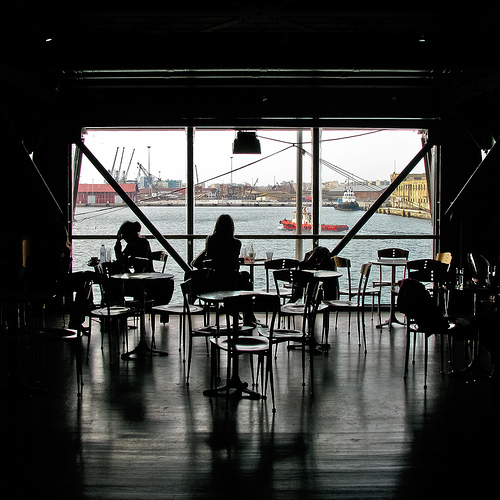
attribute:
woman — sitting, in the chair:
[188, 191, 244, 295]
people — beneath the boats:
[65, 175, 447, 297]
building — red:
[74, 173, 144, 210]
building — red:
[75, 182, 148, 212]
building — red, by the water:
[381, 167, 430, 212]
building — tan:
[384, 170, 432, 220]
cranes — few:
[111, 144, 173, 191]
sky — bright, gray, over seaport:
[175, 162, 225, 192]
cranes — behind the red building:
[113, 152, 135, 174]